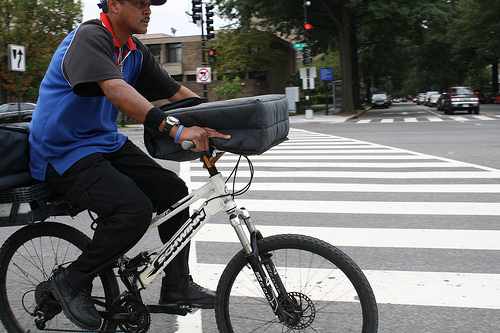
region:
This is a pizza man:
[3, 8, 398, 330]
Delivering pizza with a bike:
[9, 101, 423, 331]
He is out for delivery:
[25, 2, 195, 200]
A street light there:
[187, 1, 391, 109]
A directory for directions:
[313, 55, 340, 87]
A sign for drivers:
[182, 55, 229, 89]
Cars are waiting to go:
[369, 60, 486, 134]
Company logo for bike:
[117, 204, 224, 276]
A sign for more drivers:
[6, 23, 30, 87]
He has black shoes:
[25, 223, 180, 331]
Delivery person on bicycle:
[26, 4, 204, 312]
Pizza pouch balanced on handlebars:
[128, 54, 296, 185]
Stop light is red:
[193, 40, 234, 86]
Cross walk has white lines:
[328, 107, 456, 151]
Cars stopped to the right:
[331, 39, 484, 126]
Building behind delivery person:
[141, 28, 284, 103]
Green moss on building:
[211, 26, 261, 87]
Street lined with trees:
[304, 10, 491, 93]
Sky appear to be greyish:
[138, 0, 238, 44]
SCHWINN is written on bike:
[133, 205, 231, 276]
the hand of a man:
[179, 122, 234, 157]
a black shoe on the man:
[159, 275, 228, 313]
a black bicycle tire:
[207, 227, 377, 331]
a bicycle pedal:
[163, 292, 205, 318]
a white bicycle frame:
[138, 170, 226, 283]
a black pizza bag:
[140, 87, 293, 163]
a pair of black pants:
[43, 136, 190, 294]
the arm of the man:
[72, 32, 184, 149]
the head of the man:
[97, 0, 172, 40]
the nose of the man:
[138, 4, 155, 18]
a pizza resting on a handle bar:
[141, 76, 297, 151]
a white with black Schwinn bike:
[0, 125, 387, 325]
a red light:
[200, 42, 215, 62]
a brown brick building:
[112, 26, 294, 113]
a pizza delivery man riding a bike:
[5, 0, 225, 306]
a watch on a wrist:
[160, 108, 181, 136]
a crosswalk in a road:
[176, 121, 497, 327]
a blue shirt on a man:
[29, 23, 151, 174]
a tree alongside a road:
[329, 3, 363, 118]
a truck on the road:
[444, 80, 482, 116]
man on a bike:
[26, 0, 231, 327]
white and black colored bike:
[5, 127, 384, 331]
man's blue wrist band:
[172, 119, 185, 144]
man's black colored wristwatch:
[160, 108, 177, 143]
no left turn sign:
[194, 62, 213, 87]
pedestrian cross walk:
[166, 100, 498, 330]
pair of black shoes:
[46, 260, 228, 331]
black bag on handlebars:
[133, 90, 292, 165]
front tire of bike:
[209, 230, 383, 331]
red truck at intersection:
[439, 81, 481, 116]